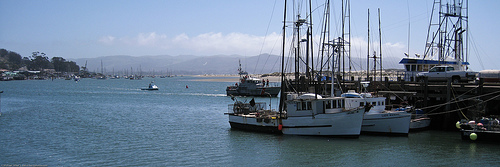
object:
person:
[144, 85, 153, 89]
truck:
[413, 64, 482, 88]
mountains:
[68, 52, 456, 76]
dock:
[227, 62, 430, 109]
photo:
[11, 6, 473, 153]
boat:
[224, 23, 367, 138]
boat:
[337, 13, 411, 138]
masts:
[304, 0, 316, 85]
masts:
[357, 7, 376, 83]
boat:
[137, 77, 159, 91]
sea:
[0, 76, 244, 115]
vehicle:
[410, 64, 483, 85]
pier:
[287, 76, 499, 101]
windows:
[322, 97, 341, 116]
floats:
[452, 121, 461, 129]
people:
[260, 76, 264, 89]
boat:
[224, 60, 283, 97]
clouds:
[111, 28, 390, 58]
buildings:
[5, 70, 71, 83]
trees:
[60, 61, 72, 72]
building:
[399, 55, 471, 82]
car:
[411, 64, 480, 84]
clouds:
[129, 31, 257, 54]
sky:
[39, 2, 262, 51]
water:
[54, 105, 173, 152]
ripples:
[112, 115, 142, 140]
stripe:
[280, 123, 335, 129]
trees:
[65, 60, 83, 72]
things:
[465, 133, 476, 141]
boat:
[455, 114, 498, 146]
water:
[0, 78, 496, 164]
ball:
[467, 132, 478, 139]